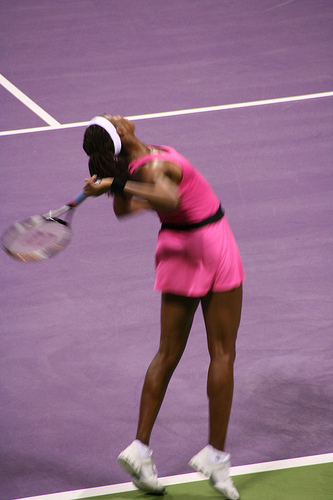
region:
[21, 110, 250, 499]
A woman playing tennis.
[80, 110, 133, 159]
White headband around woman's head.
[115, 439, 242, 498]
A pair of white tennis shoes.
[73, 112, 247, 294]
Woman wearing pink tennis outfit.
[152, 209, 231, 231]
Black belt on tennis outfit.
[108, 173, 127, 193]
Black wristband on right wrist.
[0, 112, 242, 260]
Woman holding tennis racquet in right hand.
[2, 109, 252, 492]
Woman getting ready to hit tennis ball.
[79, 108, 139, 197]
Woman's hair pulled back on head.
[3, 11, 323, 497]
Tennis court with white stripes.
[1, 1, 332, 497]
tennis court with white lines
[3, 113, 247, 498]
player bending back to swing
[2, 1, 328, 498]
purple surface of court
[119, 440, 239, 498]
feet on top toes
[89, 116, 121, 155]
white band on head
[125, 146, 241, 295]
pink skirt on player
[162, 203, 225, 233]
black belt on outfit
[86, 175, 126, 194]
black band on wrist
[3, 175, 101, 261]
hand holding tennis racket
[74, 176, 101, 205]
hand on blue grip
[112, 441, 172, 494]
SHOE ON THE FOOT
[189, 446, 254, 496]
shoe on the foot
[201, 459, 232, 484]
the shoe is white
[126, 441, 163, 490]
the shoe is white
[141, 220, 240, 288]
skirt on the woman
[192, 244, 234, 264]
the skirt is pink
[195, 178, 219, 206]
tank on the woman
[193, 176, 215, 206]
the tank is pink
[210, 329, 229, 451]
leg of the woman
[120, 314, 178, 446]
leg of the woman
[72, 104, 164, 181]
head of a person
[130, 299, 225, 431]
leg of a person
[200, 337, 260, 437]
leg of a person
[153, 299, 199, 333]
thigh of a person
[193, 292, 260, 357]
thigh of a person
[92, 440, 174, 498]
feet of a person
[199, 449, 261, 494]
feet of a person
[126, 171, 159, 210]
arm of a person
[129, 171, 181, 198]
an arm of a person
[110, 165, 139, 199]
wrist of a person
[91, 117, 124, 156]
white headband on tennis player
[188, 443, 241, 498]
right shoe on tennis player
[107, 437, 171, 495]
left shoe on tennis player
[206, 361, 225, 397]
right calf muscle on woman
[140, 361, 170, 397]
the woman's left calf muscle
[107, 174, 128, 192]
black wristband on arm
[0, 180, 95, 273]
tennis raquet in her hand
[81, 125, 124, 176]
braids in her hair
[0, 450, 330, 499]
white lines on the court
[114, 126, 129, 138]
the woman's right ear